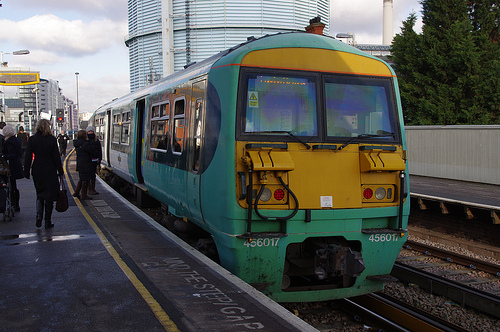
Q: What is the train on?
A: Tracks.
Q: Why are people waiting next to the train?
A: To board the train.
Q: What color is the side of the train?
A: Green.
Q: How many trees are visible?
A: One.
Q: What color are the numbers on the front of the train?
A: White.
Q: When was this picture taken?
A: During the day.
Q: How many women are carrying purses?
A: One.